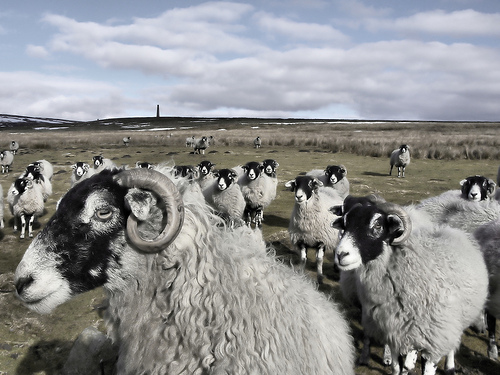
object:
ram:
[12, 160, 491, 375]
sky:
[0, 0, 500, 124]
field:
[6, 147, 496, 371]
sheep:
[0, 126, 498, 374]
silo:
[156, 102, 163, 116]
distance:
[0, 61, 500, 151]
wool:
[169, 260, 304, 357]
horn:
[113, 162, 185, 252]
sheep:
[7, 171, 49, 244]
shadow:
[13, 212, 41, 234]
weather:
[5, 7, 494, 372]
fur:
[411, 251, 468, 304]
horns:
[21, 154, 499, 277]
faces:
[12, 175, 398, 300]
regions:
[15, 176, 388, 315]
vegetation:
[5, 132, 500, 165]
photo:
[0, 1, 496, 375]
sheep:
[379, 141, 421, 182]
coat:
[386, 142, 415, 182]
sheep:
[13, 165, 356, 374]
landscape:
[9, 129, 500, 374]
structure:
[148, 98, 169, 118]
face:
[10, 175, 27, 199]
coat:
[4, 173, 60, 245]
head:
[4, 150, 219, 325]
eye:
[88, 200, 121, 230]